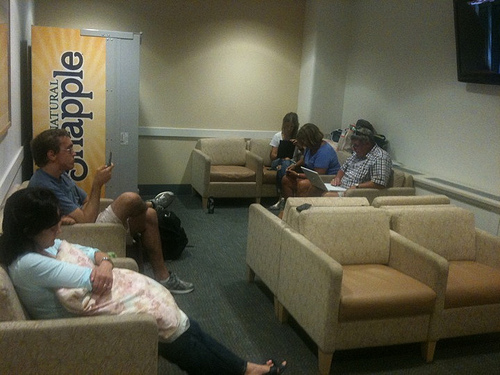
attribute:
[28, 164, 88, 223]
shirt — blue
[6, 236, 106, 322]
shirt — blue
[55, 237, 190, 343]
pillow — pink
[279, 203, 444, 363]
chair — empty, tan, brown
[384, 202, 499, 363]
chair — brown, empty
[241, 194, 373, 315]
chair — brown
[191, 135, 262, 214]
chair — brown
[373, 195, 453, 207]
chair — brown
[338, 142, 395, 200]
shirt — plaid, button down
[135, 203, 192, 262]
backpack — black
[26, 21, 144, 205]
vending machine — for snapple, large, cold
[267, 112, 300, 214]
person — reading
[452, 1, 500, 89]
tv — flat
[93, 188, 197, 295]
legs — crossed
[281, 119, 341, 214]
woman — looking down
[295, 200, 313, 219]
remote control — black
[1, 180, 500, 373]
carpet — greenish grey